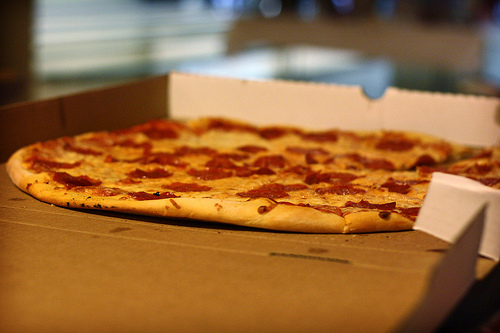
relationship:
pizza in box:
[3, 114, 500, 232] [1, 70, 498, 331]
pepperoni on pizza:
[55, 132, 450, 203] [3, 114, 500, 232]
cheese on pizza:
[52, 125, 470, 203] [3, 114, 500, 232]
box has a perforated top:
[1, 70, 498, 331] [167, 68, 499, 105]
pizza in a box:
[3, 114, 500, 232] [1, 70, 498, 331]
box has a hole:
[1, 70, 498, 331] [359, 85, 390, 105]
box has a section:
[1, 70, 498, 331] [0, 207, 495, 285]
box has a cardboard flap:
[1, 70, 498, 331] [411, 171, 499, 262]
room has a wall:
[1, 0, 500, 108] [1, 0, 35, 103]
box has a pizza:
[1, 70, 498, 331] [3, 114, 500, 232]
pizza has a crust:
[3, 114, 500, 232] [3, 141, 421, 233]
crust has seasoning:
[3, 141, 421, 233] [52, 189, 123, 212]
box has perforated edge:
[1, 70, 498, 331] [4, 65, 497, 117]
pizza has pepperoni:
[3, 114, 500, 232] [55, 132, 450, 203]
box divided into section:
[1, 70, 498, 331] [0, 207, 495, 285]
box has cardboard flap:
[1, 70, 498, 331] [411, 171, 499, 262]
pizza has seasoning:
[3, 114, 500, 232] [52, 189, 123, 212]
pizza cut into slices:
[3, 114, 500, 232] [6, 115, 499, 231]